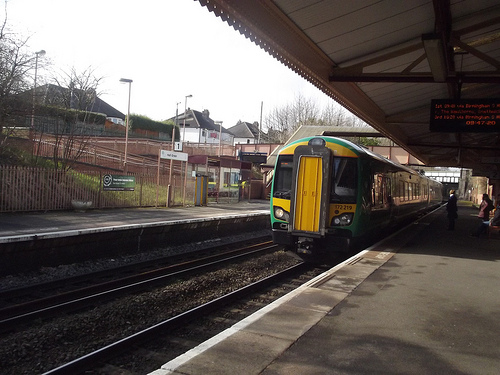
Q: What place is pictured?
A: It is a station.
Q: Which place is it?
A: It is a station.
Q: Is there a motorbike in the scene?
A: No, there are no motorcycles.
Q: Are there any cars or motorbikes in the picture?
A: No, there are no motorbikes or cars.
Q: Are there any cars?
A: No, there are no cars.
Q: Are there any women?
A: Yes, there is a woman.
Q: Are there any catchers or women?
A: Yes, there is a woman.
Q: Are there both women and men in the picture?
A: Yes, there are both a woman and a man.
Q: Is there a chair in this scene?
A: No, there are no chairs.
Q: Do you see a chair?
A: No, there are no chairs.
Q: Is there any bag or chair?
A: No, there are no chairs or bags.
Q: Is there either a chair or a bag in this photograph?
A: No, there are no chairs or bags.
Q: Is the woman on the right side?
A: Yes, the woman is on the right of the image.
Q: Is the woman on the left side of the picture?
A: No, the woman is on the right of the image.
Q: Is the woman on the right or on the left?
A: The woman is on the right of the image.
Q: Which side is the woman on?
A: The woman is on the right of the image.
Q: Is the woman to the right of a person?
A: Yes, the woman is to the right of a person.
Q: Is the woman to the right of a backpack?
A: No, the woman is to the right of a person.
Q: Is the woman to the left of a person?
A: No, the woman is to the right of a person.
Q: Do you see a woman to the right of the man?
A: Yes, there is a woman to the right of the man.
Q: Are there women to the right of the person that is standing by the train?
A: Yes, there is a woman to the right of the man.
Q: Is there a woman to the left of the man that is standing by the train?
A: No, the woman is to the right of the man.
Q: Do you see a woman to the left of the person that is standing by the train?
A: No, the woman is to the right of the man.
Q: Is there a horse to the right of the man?
A: No, there is a woman to the right of the man.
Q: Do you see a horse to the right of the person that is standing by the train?
A: No, there is a woman to the right of the man.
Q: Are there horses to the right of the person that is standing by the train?
A: No, there is a woman to the right of the man.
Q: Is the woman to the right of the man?
A: Yes, the woman is to the right of the man.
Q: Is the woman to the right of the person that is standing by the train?
A: Yes, the woman is to the right of the man.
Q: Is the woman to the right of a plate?
A: No, the woman is to the right of the man.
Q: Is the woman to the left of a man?
A: No, the woman is to the right of a man.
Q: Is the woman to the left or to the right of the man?
A: The woman is to the right of the man.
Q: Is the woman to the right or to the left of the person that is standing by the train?
A: The woman is to the right of the man.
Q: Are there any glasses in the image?
A: No, there are no glasses.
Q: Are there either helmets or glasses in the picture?
A: No, there are no glasses or helmets.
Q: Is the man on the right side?
A: Yes, the man is on the right of the image.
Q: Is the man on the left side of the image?
A: No, the man is on the right of the image.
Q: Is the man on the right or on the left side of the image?
A: The man is on the right of the image.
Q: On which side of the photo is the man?
A: The man is on the right of the image.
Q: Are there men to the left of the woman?
A: Yes, there is a man to the left of the woman.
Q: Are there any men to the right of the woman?
A: No, the man is to the left of the woman.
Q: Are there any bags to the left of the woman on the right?
A: No, there is a man to the left of the woman.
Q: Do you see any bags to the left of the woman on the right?
A: No, there is a man to the left of the woman.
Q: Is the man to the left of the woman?
A: Yes, the man is to the left of the woman.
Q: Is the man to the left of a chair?
A: No, the man is to the left of the woman.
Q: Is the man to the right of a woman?
A: No, the man is to the left of a woman.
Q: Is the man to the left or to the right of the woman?
A: The man is to the left of the woman.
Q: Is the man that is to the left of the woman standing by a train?
A: Yes, the man is standing by a train.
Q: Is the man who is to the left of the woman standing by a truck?
A: No, the man is standing by a train.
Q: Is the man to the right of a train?
A: Yes, the man is to the right of a train.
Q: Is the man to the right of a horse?
A: No, the man is to the right of a train.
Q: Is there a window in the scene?
A: Yes, there is a window.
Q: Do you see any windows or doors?
A: Yes, there is a window.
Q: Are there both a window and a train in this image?
A: Yes, there are both a window and a train.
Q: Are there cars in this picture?
A: No, there are no cars.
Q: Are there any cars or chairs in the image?
A: No, there are no cars or chairs.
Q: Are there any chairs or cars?
A: No, there are no cars or chairs.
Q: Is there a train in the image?
A: Yes, there is a train.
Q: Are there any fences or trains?
A: Yes, there is a train.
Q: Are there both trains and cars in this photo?
A: No, there is a train but no cars.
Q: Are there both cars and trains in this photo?
A: No, there is a train but no cars.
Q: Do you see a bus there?
A: No, there are no buses.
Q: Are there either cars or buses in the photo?
A: No, there are no buses or cars.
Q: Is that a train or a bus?
A: That is a train.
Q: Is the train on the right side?
A: Yes, the train is on the right of the image.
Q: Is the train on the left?
A: No, the train is on the right of the image.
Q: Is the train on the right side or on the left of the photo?
A: The train is on the right of the image.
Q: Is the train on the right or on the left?
A: The train is on the right of the image.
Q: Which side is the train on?
A: The train is on the right of the image.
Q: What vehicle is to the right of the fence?
A: The vehicle is a train.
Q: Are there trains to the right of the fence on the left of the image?
A: Yes, there is a train to the right of the fence.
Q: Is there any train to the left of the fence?
A: No, the train is to the right of the fence.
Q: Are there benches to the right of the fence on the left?
A: No, there is a train to the right of the fence.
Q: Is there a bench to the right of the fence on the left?
A: No, there is a train to the right of the fence.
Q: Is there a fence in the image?
A: Yes, there is a fence.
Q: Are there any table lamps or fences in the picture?
A: Yes, there is a fence.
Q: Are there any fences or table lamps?
A: Yes, there is a fence.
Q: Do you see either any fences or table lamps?
A: Yes, there is a fence.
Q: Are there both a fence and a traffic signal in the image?
A: No, there is a fence but no traffic lights.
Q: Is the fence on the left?
A: Yes, the fence is on the left of the image.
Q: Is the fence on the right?
A: No, the fence is on the left of the image.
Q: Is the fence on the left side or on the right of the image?
A: The fence is on the left of the image.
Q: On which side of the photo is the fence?
A: The fence is on the left of the image.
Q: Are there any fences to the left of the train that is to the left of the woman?
A: Yes, there is a fence to the left of the train.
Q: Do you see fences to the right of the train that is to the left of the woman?
A: No, the fence is to the left of the train.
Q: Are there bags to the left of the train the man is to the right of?
A: No, there is a fence to the left of the train.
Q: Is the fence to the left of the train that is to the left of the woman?
A: Yes, the fence is to the left of the train.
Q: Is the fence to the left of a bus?
A: No, the fence is to the left of the train.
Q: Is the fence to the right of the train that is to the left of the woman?
A: No, the fence is to the left of the train.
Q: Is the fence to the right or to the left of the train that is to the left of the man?
A: The fence is to the left of the train.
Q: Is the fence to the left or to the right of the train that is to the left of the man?
A: The fence is to the left of the train.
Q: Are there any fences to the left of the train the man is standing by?
A: Yes, there is a fence to the left of the train.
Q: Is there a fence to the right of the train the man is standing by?
A: No, the fence is to the left of the train.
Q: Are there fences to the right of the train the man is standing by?
A: No, the fence is to the left of the train.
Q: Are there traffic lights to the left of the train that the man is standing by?
A: No, there is a fence to the left of the train.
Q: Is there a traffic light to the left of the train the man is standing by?
A: No, there is a fence to the left of the train.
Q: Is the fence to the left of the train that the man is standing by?
A: Yes, the fence is to the left of the train.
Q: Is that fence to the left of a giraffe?
A: No, the fence is to the left of the train.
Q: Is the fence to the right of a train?
A: No, the fence is to the left of a train.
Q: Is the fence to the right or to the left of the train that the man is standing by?
A: The fence is to the left of the train.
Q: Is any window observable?
A: Yes, there is a window.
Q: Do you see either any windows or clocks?
A: Yes, there is a window.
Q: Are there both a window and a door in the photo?
A: Yes, there are both a window and a door.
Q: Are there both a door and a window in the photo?
A: Yes, there are both a window and a door.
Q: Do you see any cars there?
A: No, there are no cars.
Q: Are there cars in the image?
A: No, there are no cars.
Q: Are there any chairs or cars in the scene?
A: No, there are no cars or chairs.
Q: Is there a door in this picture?
A: Yes, there is a door.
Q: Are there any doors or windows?
A: Yes, there is a door.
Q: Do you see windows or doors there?
A: Yes, there is a door.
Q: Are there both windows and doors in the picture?
A: Yes, there are both a door and windows.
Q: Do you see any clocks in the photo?
A: No, there are no clocks.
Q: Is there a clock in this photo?
A: No, there are no clocks.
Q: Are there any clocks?
A: No, there are no clocks.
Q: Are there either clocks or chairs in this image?
A: No, there are no clocks or chairs.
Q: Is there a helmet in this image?
A: No, there are no helmets.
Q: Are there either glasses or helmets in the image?
A: No, there are no helmets or glasses.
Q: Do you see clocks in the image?
A: No, there are no clocks.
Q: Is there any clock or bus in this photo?
A: No, there are no clocks or buses.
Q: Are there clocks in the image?
A: No, there are no clocks.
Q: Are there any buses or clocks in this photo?
A: No, there are no clocks or buses.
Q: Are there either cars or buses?
A: No, there are no cars or buses.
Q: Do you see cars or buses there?
A: No, there are no cars or buses.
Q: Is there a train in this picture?
A: Yes, there is a train.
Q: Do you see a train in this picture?
A: Yes, there is a train.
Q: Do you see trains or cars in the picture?
A: Yes, there is a train.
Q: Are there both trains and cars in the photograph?
A: No, there is a train but no cars.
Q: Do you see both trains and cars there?
A: No, there is a train but no cars.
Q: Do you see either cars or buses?
A: No, there are no cars or buses.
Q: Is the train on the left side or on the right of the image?
A: The train is on the right of the image.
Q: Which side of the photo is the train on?
A: The train is on the right of the image.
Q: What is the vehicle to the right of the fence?
A: The vehicle is a train.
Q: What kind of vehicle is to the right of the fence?
A: The vehicle is a train.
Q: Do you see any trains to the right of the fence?
A: Yes, there is a train to the right of the fence.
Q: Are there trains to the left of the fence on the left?
A: No, the train is to the right of the fence.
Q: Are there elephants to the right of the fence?
A: No, there is a train to the right of the fence.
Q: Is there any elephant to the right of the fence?
A: No, there is a train to the right of the fence.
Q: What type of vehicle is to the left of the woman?
A: The vehicle is a train.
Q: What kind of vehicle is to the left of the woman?
A: The vehicle is a train.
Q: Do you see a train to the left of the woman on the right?
A: Yes, there is a train to the left of the woman.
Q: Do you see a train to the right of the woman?
A: No, the train is to the left of the woman.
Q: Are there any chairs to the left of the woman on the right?
A: No, there is a train to the left of the woman.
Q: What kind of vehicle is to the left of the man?
A: The vehicle is a train.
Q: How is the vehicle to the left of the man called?
A: The vehicle is a train.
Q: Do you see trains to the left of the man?
A: Yes, there is a train to the left of the man.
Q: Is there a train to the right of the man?
A: No, the train is to the left of the man.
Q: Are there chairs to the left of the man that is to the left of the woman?
A: No, there is a train to the left of the man.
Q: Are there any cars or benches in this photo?
A: No, there are no cars or benches.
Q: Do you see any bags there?
A: No, there are no bags.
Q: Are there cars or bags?
A: No, there are no bags or cars.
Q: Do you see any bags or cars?
A: No, there are no bags or cars.